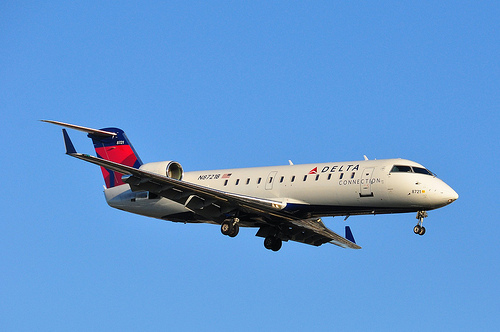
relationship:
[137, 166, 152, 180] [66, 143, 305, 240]
light on airplane wings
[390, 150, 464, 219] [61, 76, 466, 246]
nose on plane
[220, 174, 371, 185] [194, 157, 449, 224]
windows on plane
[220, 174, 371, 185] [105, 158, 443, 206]
windows on side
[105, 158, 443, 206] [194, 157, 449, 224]
side on plane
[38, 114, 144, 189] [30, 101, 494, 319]
tail on plane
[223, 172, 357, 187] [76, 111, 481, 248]
windows on plane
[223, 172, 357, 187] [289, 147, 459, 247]
windows on front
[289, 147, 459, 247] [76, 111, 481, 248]
front on plane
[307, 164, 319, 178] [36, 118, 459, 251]
red symbol on airplane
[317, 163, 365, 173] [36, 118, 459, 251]
delta name on airplane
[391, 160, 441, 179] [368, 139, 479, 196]
window in pilot's cockpit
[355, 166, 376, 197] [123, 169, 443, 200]
door on side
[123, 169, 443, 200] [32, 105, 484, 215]
side on plane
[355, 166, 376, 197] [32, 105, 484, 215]
door on plane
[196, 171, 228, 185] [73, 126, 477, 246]
number on plane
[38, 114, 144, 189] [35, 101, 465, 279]
tail of plane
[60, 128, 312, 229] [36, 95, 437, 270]
airplane wings on plane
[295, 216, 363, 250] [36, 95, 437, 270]
left wing on plane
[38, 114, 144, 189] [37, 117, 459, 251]
tail of airplane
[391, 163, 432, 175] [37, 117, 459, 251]
pilot windows of airplane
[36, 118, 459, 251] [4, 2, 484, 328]
airplane in sky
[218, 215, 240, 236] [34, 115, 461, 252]
wheel of plane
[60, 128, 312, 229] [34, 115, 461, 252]
airplane wings of plane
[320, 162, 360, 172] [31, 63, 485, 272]
delta name of plane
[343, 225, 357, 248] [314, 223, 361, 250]
tip of left wing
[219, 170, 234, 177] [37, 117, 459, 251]
flag on airplane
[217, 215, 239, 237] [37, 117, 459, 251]
wheels on airplane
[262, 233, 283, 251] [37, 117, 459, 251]
wheels on airplane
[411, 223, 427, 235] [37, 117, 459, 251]
wheels on airplane